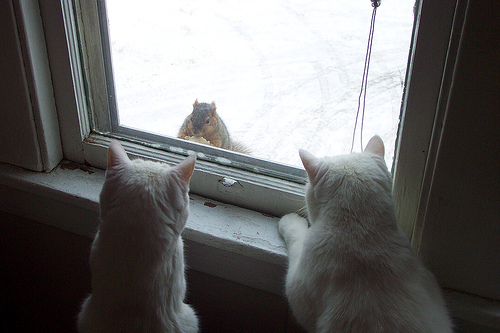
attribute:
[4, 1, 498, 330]
house — scene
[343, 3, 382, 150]
strings — hanging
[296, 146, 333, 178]
ear — pink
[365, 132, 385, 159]
ear — pink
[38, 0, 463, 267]
window — white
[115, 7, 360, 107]
snow — white 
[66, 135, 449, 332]
cats — in the stands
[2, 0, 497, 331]
scene — daytime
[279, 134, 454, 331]
cat — white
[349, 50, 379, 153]
string — white 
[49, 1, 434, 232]
window — sill